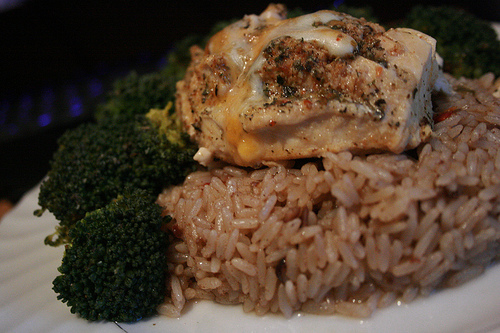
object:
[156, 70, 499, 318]
rice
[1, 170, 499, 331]
plate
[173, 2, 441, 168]
chicken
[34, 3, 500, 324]
broccoli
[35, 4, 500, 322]
food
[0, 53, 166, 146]
fire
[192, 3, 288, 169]
small bone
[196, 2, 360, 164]
cheese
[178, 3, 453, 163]
toppings